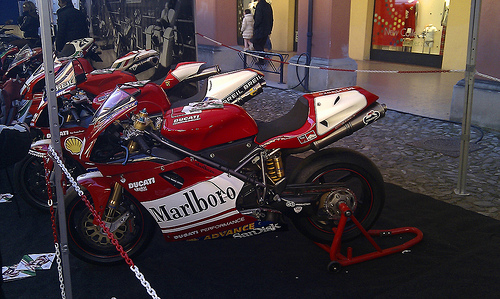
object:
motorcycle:
[53, 87, 386, 266]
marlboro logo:
[145, 186, 238, 221]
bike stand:
[311, 201, 426, 274]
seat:
[246, 91, 313, 152]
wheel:
[282, 145, 387, 244]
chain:
[40, 145, 163, 298]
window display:
[369, 0, 449, 56]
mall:
[232, 0, 499, 70]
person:
[240, 7, 259, 50]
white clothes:
[234, 14, 255, 50]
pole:
[451, 0, 484, 199]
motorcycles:
[1, 35, 387, 266]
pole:
[33, 0, 82, 299]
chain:
[189, 30, 499, 92]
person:
[252, 0, 275, 67]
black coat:
[248, 2, 276, 40]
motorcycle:
[11, 68, 266, 215]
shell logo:
[61, 133, 86, 157]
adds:
[62, 135, 284, 244]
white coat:
[237, 13, 256, 41]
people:
[15, 1, 279, 65]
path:
[194, 79, 499, 220]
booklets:
[2, 251, 58, 289]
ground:
[0, 46, 499, 298]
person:
[16, 2, 40, 43]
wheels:
[17, 140, 386, 267]